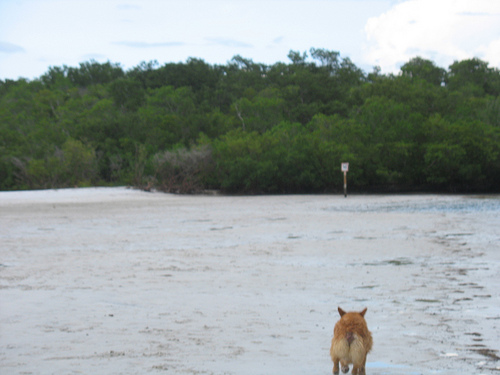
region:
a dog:
[227, 307, 410, 371]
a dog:
[321, 212, 411, 364]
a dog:
[295, 234, 357, 356]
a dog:
[321, 292, 361, 364]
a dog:
[298, 271, 385, 366]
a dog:
[268, 156, 383, 367]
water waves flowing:
[400, 216, 490, 362]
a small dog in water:
[324, 299, 379, 374]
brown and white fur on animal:
[323, 297, 374, 374]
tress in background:
[2, 80, 497, 182]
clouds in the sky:
[356, 1, 491, 53]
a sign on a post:
[337, 155, 349, 196]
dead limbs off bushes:
[153, 154, 200, 189]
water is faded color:
[48, 240, 175, 314]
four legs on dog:
[328, 355, 372, 374]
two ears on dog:
[333, 305, 373, 315]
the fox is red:
[325, 300, 390, 374]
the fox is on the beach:
[310, 292, 378, 372]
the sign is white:
[337, 158, 358, 199]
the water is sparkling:
[307, 191, 497, 217]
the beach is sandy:
[0, 185, 499, 372]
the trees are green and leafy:
[0, 45, 498, 203]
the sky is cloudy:
[0, 0, 497, 85]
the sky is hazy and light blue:
[0, 0, 497, 100]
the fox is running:
[318, 302, 379, 374]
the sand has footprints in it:
[415, 219, 497, 374]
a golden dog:
[229, 207, 371, 369]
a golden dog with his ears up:
[257, 243, 449, 368]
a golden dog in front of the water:
[299, 272, 369, 371]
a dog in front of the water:
[287, 264, 439, 373]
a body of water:
[75, 190, 332, 341]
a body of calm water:
[83, 232, 285, 335]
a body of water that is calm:
[107, 221, 277, 371]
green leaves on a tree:
[172, 42, 490, 174]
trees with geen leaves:
[222, 70, 472, 207]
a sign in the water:
[300, 149, 436, 245]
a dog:
[317, 298, 377, 363]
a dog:
[307, 221, 402, 372]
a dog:
[297, 291, 377, 368]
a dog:
[291, 295, 382, 365]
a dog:
[311, 275, 402, 367]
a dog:
[322, 281, 364, 372]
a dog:
[327, 311, 382, 353]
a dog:
[327, 294, 361, 369]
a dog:
[310, 280, 367, 328]